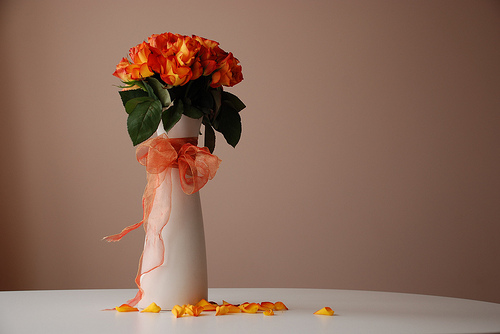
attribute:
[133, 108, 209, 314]
vase — white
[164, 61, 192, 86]
flower — orange, beautiful, rose, orange tipped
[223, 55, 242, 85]
flower — orange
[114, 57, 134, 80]
flower — orange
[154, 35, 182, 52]
flower — orange, red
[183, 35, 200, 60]
flower — orange, yellow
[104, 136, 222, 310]
ribbon — orange, organza, pink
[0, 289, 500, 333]
table — white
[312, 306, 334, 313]
petal — yellow, orange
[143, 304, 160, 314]
petal — yellow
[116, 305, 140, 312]
petal — yellow, rose, orange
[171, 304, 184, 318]
petal — yellow, rose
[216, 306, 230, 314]
petal — yellow, orange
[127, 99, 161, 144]
leaf — green, shiny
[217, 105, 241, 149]
leaf — green, dark green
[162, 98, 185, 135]
leaf — green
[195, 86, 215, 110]
leaf — green, dark green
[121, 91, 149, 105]
leaf — green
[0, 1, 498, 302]
wall — pink